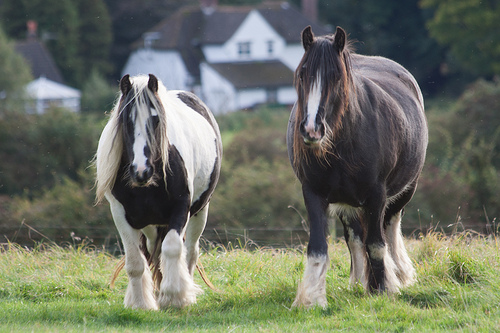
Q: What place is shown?
A: It is a field.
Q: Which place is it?
A: It is a field.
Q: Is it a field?
A: Yes, it is a field.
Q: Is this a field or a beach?
A: It is a field.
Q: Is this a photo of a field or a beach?
A: It is showing a field.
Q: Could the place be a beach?
A: No, it is a field.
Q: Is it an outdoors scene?
A: Yes, it is outdoors.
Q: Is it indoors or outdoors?
A: It is outdoors.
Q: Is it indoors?
A: No, it is outdoors.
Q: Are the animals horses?
A: Yes, all the animals are horses.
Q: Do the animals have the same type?
A: Yes, all the animals are horses.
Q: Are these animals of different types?
A: No, all the animals are horses.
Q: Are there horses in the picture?
A: Yes, there is a horse.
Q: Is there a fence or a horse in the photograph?
A: Yes, there is a horse.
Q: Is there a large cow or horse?
A: Yes, there is a large horse.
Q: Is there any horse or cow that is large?
A: Yes, the horse is large.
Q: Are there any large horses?
A: Yes, there is a large horse.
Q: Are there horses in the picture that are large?
A: Yes, there is a horse that is large.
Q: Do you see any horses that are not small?
A: Yes, there is a large horse.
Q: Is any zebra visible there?
A: No, there are no zebras.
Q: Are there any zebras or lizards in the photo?
A: No, there are no zebras or lizards.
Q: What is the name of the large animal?
A: The animal is a horse.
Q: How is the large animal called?
A: The animal is a horse.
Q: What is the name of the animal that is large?
A: The animal is a horse.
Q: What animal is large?
A: The animal is a horse.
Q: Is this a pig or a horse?
A: This is a horse.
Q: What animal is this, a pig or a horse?
A: This is a horse.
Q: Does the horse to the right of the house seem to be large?
A: Yes, the horse is large.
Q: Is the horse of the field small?
A: No, the horse is large.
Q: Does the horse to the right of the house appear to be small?
A: No, the horse is large.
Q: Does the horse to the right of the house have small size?
A: No, the horse is large.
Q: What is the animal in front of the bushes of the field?
A: The animal is a horse.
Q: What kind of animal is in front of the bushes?
A: The animal is a horse.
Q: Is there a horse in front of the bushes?
A: Yes, there is a horse in front of the bushes.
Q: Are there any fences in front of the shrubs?
A: No, there is a horse in front of the shrubs.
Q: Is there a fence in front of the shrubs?
A: No, there is a horse in front of the shrubs.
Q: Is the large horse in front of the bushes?
A: Yes, the horse is in front of the bushes.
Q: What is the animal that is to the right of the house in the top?
A: The animal is a horse.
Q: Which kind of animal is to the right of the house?
A: The animal is a horse.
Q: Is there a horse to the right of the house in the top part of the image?
A: Yes, there is a horse to the right of the house.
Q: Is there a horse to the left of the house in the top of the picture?
A: No, the horse is to the right of the house.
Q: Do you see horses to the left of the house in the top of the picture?
A: No, the horse is to the right of the house.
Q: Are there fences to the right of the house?
A: No, there is a horse to the right of the house.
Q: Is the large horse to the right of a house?
A: Yes, the horse is to the right of a house.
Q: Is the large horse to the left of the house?
A: No, the horse is to the right of the house.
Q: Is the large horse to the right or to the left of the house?
A: The horse is to the right of the house.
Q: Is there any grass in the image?
A: Yes, there is grass.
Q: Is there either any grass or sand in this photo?
A: Yes, there is grass.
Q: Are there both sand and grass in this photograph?
A: No, there is grass but no sand.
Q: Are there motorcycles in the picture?
A: No, there are no motorcycles.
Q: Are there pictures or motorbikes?
A: No, there are no motorbikes or pictures.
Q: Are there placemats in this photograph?
A: No, there are no placemats.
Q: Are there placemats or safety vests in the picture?
A: No, there are no placemats or safety vests.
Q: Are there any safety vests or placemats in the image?
A: No, there are no placemats or safety vests.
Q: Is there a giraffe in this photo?
A: No, there are no giraffes.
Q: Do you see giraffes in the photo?
A: No, there are no giraffes.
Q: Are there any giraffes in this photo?
A: No, there are no giraffes.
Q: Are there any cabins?
A: No, there are no cabins.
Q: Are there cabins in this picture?
A: No, there are no cabins.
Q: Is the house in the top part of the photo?
A: Yes, the house is in the top of the image.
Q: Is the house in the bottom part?
A: No, the house is in the top of the image.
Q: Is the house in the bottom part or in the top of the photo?
A: The house is in the top of the image.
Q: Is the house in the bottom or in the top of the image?
A: The house is in the top of the image.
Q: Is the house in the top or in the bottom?
A: The house is in the top of the image.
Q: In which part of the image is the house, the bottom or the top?
A: The house is in the top of the image.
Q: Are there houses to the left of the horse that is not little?
A: Yes, there is a house to the left of the horse.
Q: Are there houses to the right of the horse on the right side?
A: No, the house is to the left of the horse.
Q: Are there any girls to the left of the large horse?
A: No, there is a house to the left of the horse.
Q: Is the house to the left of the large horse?
A: Yes, the house is to the left of the horse.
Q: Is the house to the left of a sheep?
A: No, the house is to the left of the horse.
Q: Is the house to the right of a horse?
A: No, the house is to the left of a horse.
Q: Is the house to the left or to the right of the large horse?
A: The house is to the left of the horse.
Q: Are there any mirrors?
A: No, there are no mirrors.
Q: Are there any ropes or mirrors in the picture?
A: No, there are no mirrors or ropes.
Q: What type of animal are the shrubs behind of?
A: The shrubs are behind the horse.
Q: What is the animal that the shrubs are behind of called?
A: The animal is a horse.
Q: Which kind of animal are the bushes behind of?
A: The shrubs are behind the horse.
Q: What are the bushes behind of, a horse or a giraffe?
A: The bushes are behind a horse.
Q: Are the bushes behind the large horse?
A: Yes, the bushes are behind the horse.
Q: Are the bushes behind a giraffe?
A: No, the bushes are behind the horse.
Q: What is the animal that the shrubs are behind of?
A: The animal is a horse.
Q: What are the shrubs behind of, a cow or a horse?
A: The shrubs are behind a horse.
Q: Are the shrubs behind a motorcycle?
A: No, the shrubs are behind the horse.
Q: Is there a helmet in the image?
A: No, there are no helmets.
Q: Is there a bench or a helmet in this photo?
A: No, there are no helmets or benches.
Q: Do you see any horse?
A: Yes, there is a horse.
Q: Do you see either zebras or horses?
A: Yes, there is a horse.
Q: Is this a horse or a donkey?
A: This is a horse.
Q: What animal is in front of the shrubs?
A: The horse is in front of the shrubs.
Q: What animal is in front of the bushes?
A: The horse is in front of the shrubs.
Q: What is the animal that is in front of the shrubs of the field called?
A: The animal is a horse.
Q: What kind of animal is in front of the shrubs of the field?
A: The animal is a horse.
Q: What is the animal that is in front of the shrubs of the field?
A: The animal is a horse.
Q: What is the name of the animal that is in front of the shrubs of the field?
A: The animal is a horse.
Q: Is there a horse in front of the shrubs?
A: Yes, there is a horse in front of the shrubs.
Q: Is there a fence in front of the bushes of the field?
A: No, there is a horse in front of the shrubs.